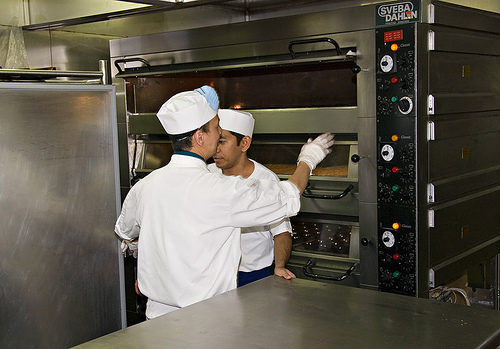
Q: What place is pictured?
A: It is a restaurant.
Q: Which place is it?
A: It is a restaurant.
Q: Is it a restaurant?
A: Yes, it is a restaurant.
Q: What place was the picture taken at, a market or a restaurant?
A: It was taken at a restaurant.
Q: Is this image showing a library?
A: No, the picture is showing a restaurant.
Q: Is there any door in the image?
A: Yes, there is a door.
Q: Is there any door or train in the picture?
A: Yes, there is a door.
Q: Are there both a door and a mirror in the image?
A: No, there is a door but no mirrors.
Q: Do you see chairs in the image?
A: No, there are no chairs.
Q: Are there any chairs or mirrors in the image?
A: No, there are no chairs or mirrors.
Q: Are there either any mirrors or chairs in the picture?
A: No, there are no chairs or mirrors.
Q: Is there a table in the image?
A: Yes, there is a table.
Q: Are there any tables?
A: Yes, there is a table.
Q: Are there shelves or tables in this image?
A: Yes, there is a table.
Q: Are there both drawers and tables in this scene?
A: No, there is a table but no drawers.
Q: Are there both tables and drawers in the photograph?
A: No, there is a table but no drawers.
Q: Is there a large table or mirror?
A: Yes, there is a large table.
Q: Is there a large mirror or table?
A: Yes, there is a large table.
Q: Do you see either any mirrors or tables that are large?
A: Yes, the table is large.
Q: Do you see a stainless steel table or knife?
A: Yes, there is a stainless steel table.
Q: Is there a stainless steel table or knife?
A: Yes, there is a stainless steel table.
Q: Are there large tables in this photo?
A: Yes, there is a large table.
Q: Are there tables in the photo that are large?
A: Yes, there is a table that is large.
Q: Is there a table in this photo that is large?
A: Yes, there is a table that is large.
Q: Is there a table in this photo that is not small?
A: Yes, there is a large table.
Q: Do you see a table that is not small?
A: Yes, there is a large table.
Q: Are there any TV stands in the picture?
A: No, there are no TV stands.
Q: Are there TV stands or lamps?
A: No, there are no TV stands or lamps.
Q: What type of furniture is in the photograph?
A: The furniture is a table.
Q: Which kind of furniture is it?
A: The piece of furniture is a table.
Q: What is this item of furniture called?
A: This is a table.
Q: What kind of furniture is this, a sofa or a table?
A: This is a table.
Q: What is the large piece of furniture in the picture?
A: The piece of furniture is a table.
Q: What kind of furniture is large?
A: The furniture is a table.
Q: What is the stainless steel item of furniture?
A: The piece of furniture is a table.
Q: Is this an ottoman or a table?
A: This is a table.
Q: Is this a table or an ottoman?
A: This is a table.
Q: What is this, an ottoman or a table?
A: This is a table.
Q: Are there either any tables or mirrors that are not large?
A: No, there is a table but it is large.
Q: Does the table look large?
A: Yes, the table is large.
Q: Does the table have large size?
A: Yes, the table is large.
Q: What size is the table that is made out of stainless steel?
A: The table is large.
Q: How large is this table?
A: The table is large.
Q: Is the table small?
A: No, the table is large.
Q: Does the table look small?
A: No, the table is large.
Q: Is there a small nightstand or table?
A: No, there is a table but it is large.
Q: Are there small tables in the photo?
A: No, there is a table but it is large.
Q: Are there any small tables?
A: No, there is a table but it is large.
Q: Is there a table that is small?
A: No, there is a table but it is large.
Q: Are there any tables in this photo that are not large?
A: No, there is a table but it is large.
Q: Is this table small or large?
A: The table is large.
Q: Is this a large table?
A: Yes, this is a large table.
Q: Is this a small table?
A: No, this is a large table.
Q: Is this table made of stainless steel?
A: Yes, the table is made of stainless steel.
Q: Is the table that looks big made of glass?
A: No, the table is made of stainless steel.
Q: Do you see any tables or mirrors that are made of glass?
A: No, there is a table but it is made of stainless steel.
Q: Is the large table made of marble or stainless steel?
A: The table is made of stainless steel.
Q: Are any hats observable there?
A: Yes, there is a hat.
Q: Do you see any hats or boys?
A: Yes, there is a hat.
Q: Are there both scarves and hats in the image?
A: No, there is a hat but no scarves.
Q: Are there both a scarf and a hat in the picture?
A: No, there is a hat but no scarves.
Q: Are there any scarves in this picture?
A: No, there are no scarves.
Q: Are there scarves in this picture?
A: No, there are no scarves.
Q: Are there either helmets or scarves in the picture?
A: No, there are no scarves or helmets.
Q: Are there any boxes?
A: No, there are no boxes.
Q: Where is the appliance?
A: The appliance is in the restaurant.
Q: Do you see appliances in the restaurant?
A: Yes, there is an appliance in the restaurant.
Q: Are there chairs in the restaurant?
A: No, there is an appliance in the restaurant.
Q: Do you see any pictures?
A: No, there are no pictures.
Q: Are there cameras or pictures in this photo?
A: No, there are no pictures or cameras.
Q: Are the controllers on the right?
A: Yes, the controllers are on the right of the image.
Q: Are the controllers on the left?
A: No, the controllers are on the right of the image.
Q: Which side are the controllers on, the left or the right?
A: The controllers are on the right of the image.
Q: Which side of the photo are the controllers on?
A: The controllers are on the right of the image.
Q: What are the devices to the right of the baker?
A: The devices are controllers.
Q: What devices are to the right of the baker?
A: The devices are controllers.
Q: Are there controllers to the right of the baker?
A: Yes, there are controllers to the right of the baker.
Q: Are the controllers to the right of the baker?
A: Yes, the controllers are to the right of the baker.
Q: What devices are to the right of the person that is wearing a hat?
A: The devices are controllers.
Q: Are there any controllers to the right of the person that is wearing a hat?
A: Yes, there are controllers to the right of the person.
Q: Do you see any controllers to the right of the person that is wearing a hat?
A: Yes, there are controllers to the right of the person.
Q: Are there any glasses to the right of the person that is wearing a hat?
A: No, there are controllers to the right of the person.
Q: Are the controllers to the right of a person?
A: Yes, the controllers are to the right of a person.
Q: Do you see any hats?
A: Yes, there is a hat.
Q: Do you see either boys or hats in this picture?
A: Yes, there is a hat.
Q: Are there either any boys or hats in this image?
A: Yes, there is a hat.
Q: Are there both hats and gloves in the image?
A: Yes, there are both a hat and gloves.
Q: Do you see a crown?
A: No, there are no crowns.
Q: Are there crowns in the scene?
A: No, there are no crowns.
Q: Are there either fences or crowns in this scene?
A: No, there are no crowns or fences.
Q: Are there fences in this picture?
A: No, there are no fences.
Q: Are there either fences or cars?
A: No, there are no fences or cars.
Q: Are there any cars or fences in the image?
A: No, there are no fences or cars.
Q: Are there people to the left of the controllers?
A: Yes, there is a person to the left of the controllers.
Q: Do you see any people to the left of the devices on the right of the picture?
A: Yes, there is a person to the left of the controllers.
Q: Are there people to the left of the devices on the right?
A: Yes, there is a person to the left of the controllers.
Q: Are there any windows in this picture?
A: Yes, there is a window.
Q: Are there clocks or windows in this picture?
A: Yes, there is a window.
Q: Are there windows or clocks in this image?
A: Yes, there is a window.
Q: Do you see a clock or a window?
A: Yes, there is a window.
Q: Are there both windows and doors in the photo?
A: Yes, there are both a window and a door.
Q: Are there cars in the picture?
A: No, there are no cars.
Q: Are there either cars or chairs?
A: No, there are no cars or chairs.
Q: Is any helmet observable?
A: No, there are no helmets.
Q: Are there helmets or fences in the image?
A: No, there are no helmets or fences.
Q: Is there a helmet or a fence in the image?
A: No, there are no helmets or fences.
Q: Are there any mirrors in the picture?
A: No, there are no mirrors.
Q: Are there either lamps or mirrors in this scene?
A: No, there are no mirrors or lamps.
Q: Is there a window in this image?
A: Yes, there is a window.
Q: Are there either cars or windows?
A: Yes, there is a window.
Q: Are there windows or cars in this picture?
A: Yes, there is a window.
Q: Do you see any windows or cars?
A: Yes, there is a window.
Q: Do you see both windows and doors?
A: Yes, there are both a window and a door.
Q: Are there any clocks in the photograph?
A: No, there are no clocks.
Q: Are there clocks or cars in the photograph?
A: No, there are no clocks or cars.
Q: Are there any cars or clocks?
A: No, there are no clocks or cars.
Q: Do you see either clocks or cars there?
A: No, there are no clocks or cars.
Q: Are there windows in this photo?
A: Yes, there is a window.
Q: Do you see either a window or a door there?
A: Yes, there is a window.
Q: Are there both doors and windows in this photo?
A: Yes, there are both a window and doors.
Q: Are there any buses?
A: No, there are no buses.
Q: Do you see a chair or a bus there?
A: No, there are no buses or chairs.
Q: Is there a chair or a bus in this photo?
A: No, there are no buses or chairs.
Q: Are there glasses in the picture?
A: No, there are no glasses.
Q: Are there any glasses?
A: No, there are no glasses.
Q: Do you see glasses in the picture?
A: No, there are no glasses.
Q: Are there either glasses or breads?
A: No, there are no glasses or breads.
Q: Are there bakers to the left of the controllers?
A: Yes, there is a baker to the left of the controllers.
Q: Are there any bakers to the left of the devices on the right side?
A: Yes, there is a baker to the left of the controllers.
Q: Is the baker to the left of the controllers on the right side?
A: Yes, the baker is to the left of the controllers.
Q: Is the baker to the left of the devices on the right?
A: Yes, the baker is to the left of the controllers.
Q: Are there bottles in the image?
A: No, there are no bottles.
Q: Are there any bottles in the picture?
A: No, there are no bottles.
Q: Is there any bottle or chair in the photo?
A: No, there are no bottles or chairs.